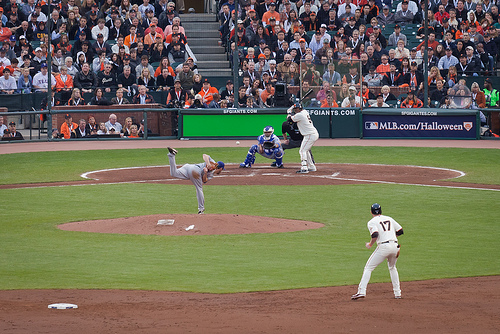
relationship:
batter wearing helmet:
[284, 85, 323, 174] [292, 102, 302, 111]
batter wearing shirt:
[284, 85, 323, 174] [289, 108, 317, 137]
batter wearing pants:
[284, 85, 323, 174] [298, 134, 318, 166]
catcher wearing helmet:
[241, 125, 285, 169] [264, 126, 275, 133]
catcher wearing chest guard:
[241, 125, 285, 169] [258, 136, 273, 153]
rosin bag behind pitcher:
[185, 223, 196, 233] [166, 145, 225, 213]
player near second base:
[351, 201, 405, 298] [46, 302, 78, 311]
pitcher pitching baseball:
[166, 145, 225, 213] [235, 139, 240, 145]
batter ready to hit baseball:
[284, 85, 323, 174] [235, 139, 240, 145]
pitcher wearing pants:
[166, 145, 225, 213] [165, 155, 208, 210]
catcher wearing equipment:
[241, 125, 285, 169] [237, 125, 285, 169]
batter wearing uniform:
[284, 85, 323, 174] [290, 111, 321, 174]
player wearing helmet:
[351, 201, 405, 298] [370, 202, 382, 216]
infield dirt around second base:
[0, 160, 498, 333] [46, 302, 78, 311]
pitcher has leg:
[166, 145, 225, 213] [165, 147, 187, 179]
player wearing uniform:
[351, 201, 405, 298] [354, 214, 406, 296]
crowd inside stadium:
[0, 0, 500, 108] [1, 0, 500, 332]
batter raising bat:
[284, 85, 323, 174] [290, 89, 313, 109]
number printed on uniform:
[379, 220, 391, 233] [354, 214, 406, 296]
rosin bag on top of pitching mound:
[185, 223, 196, 233] [58, 212, 325, 238]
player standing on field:
[351, 201, 405, 298] [0, 137, 498, 333]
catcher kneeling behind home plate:
[241, 125, 285, 169] [262, 171, 279, 176]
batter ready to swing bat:
[284, 85, 323, 174] [290, 89, 313, 109]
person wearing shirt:
[259, 2, 281, 28] [264, 11, 282, 23]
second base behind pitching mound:
[46, 302, 78, 311] [58, 212, 325, 238]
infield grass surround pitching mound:
[0, 181, 499, 291] [58, 212, 325, 238]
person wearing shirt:
[481, 78, 499, 109] [485, 89, 500, 107]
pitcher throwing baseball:
[166, 145, 225, 213] [235, 139, 240, 145]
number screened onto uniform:
[379, 220, 391, 233] [354, 214, 406, 296]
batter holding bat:
[284, 85, 323, 174] [290, 89, 313, 109]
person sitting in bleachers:
[259, 2, 281, 28] [0, 0, 499, 105]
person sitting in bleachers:
[481, 78, 499, 109] [0, 0, 499, 105]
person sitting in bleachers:
[155, 57, 173, 75] [0, 0, 499, 105]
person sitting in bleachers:
[91, 19, 109, 41] [0, 0, 499, 105]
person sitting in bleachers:
[31, 20, 49, 41] [0, 0, 499, 105]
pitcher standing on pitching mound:
[166, 145, 225, 213] [58, 212, 325, 238]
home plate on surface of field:
[262, 171, 279, 176] [0, 137, 498, 333]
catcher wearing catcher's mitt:
[241, 125, 285, 169] [262, 139, 274, 151]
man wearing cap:
[59, 112, 78, 138] [64, 114, 71, 119]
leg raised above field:
[165, 147, 187, 179] [0, 137, 498, 333]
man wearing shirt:
[436, 46, 460, 70] [436, 55, 458, 68]